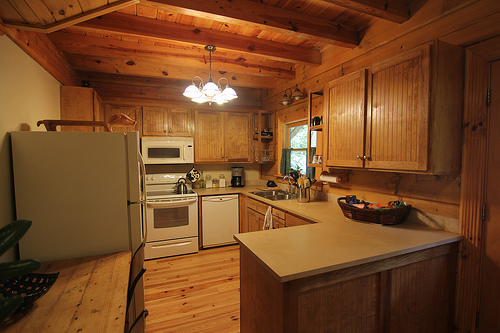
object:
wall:
[0, 33, 62, 265]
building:
[0, 0, 499, 332]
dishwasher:
[196, 192, 240, 250]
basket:
[333, 194, 411, 227]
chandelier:
[182, 43, 240, 108]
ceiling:
[0, 1, 428, 92]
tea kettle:
[172, 176, 188, 195]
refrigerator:
[6, 124, 151, 262]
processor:
[226, 165, 247, 189]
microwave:
[139, 135, 197, 166]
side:
[12, 129, 136, 264]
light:
[197, 80, 221, 100]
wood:
[137, 0, 363, 51]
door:
[201, 193, 240, 249]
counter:
[231, 186, 470, 333]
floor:
[143, 244, 241, 333]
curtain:
[304, 145, 318, 180]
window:
[283, 120, 310, 151]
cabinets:
[323, 38, 465, 177]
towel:
[259, 204, 275, 231]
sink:
[247, 188, 298, 201]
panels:
[255, 173, 462, 220]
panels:
[437, 15, 499, 51]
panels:
[142, 301, 242, 332]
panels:
[66, 250, 135, 332]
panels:
[143, 276, 238, 302]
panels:
[40, 0, 83, 22]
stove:
[140, 163, 200, 263]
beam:
[65, 15, 321, 69]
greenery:
[287, 126, 313, 168]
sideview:
[9, 130, 132, 263]